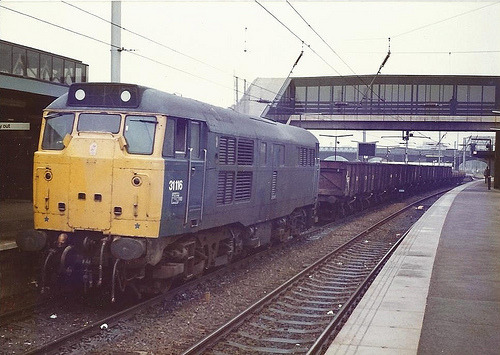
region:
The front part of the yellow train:
[14, 90, 171, 237]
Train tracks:
[205, 285, 357, 347]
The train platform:
[362, 258, 453, 353]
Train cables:
[247, 7, 429, 74]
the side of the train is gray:
[167, 99, 336, 251]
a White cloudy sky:
[148, 0, 234, 52]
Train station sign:
[2, 115, 39, 137]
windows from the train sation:
[1, 43, 94, 95]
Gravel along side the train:
[125, 311, 207, 344]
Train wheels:
[20, 232, 219, 307]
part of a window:
[444, 94, 455, 107]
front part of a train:
[141, 195, 149, 204]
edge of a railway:
[223, 290, 249, 327]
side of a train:
[277, 176, 287, 189]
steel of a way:
[299, 258, 324, 288]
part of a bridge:
[393, 122, 422, 124]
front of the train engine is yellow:
[31, 109, 172, 241]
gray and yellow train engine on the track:
[22, 81, 319, 303]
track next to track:
[177, 179, 462, 353]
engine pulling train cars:
[320, 157, 475, 221]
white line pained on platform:
[310, 175, 497, 353]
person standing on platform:
[482, 165, 490, 184]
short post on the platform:
[487, 173, 493, 190]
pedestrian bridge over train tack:
[229, 77, 498, 132]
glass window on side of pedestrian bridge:
[292, 81, 498, 121]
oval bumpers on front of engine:
[109, 239, 145, 260]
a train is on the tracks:
[33, 83, 458, 296]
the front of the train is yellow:
[32, 86, 174, 251]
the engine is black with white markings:
[39, 79, 321, 291]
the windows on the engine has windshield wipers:
[36, 104, 162, 164]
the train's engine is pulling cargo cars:
[46, 77, 454, 284]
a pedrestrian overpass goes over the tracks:
[226, 70, 498, 214]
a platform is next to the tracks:
[319, 170, 496, 347]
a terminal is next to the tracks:
[1, 40, 87, 257]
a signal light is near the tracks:
[464, 140, 480, 162]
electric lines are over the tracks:
[8, 4, 466, 257]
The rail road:
[253, 242, 343, 334]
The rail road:
[235, 170, 292, 345]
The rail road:
[181, 242, 255, 349]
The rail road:
[263, 307, 292, 352]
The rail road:
[251, 219, 293, 328]